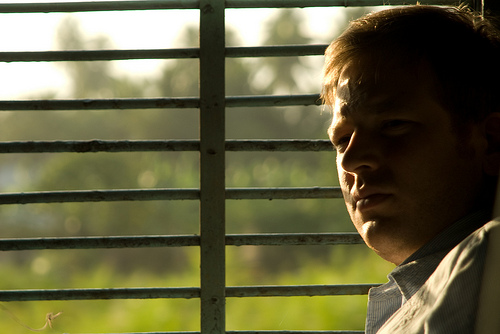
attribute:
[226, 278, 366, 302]
window pole — metalic 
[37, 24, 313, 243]
trees — group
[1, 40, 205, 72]
pole — metalic 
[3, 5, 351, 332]
window — metalic 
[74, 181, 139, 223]
pole — metalic 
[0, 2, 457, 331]
window — metalic 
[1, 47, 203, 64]
window pole — metalic 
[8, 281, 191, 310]
pole — window , metalic 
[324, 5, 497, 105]
hair — blonde 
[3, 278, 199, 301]
pole — metalic 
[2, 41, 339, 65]
bars — metal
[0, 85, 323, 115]
bars — metal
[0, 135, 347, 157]
bars — metal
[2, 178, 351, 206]
bars — metal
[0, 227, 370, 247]
bars — metal